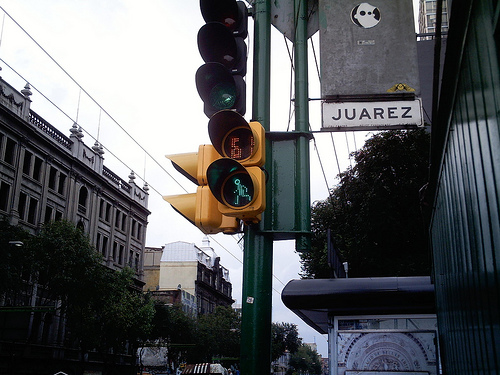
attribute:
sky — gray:
[15, 3, 342, 277]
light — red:
[211, 114, 259, 159]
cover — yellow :
[162, 108, 265, 237]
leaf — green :
[99, 311, 117, 331]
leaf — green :
[40, 257, 56, 276]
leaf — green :
[54, 241, 63, 251]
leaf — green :
[80, 271, 84, 273]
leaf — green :
[27, 254, 40, 270]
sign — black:
[323, 100, 427, 128]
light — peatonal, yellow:
[198, 109, 278, 227]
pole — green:
[238, 37, 279, 359]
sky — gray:
[1, 7, 334, 364]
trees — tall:
[38, 170, 323, 373]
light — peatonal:
[183, 132, 255, 219]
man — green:
[259, 330, 331, 374]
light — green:
[174, 90, 365, 265]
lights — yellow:
[197, 0, 244, 115]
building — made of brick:
[0, 60, 150, 364]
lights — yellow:
[148, 116, 343, 254]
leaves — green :
[98, 280, 130, 320]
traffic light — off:
[194, 3, 252, 115]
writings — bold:
[329, 103, 418, 130]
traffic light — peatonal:
[160, 126, 301, 259]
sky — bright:
[0, 1, 424, 358]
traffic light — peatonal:
[163, 106, 267, 233]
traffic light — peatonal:
[159, 111, 287, 227]